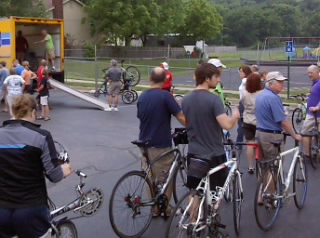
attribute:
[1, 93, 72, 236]
woman — standing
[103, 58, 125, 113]
man — standing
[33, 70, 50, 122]
girl — standing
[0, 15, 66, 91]
truck — for loading bikes on, yellow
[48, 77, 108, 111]
truck ramp — aluminum, for loading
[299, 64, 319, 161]
man — standing, balding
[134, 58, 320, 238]
people — standing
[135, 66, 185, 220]
man — balding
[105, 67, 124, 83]
shirt — gray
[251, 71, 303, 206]
man — older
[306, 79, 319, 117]
shirt — purple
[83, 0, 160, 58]
tree — leafy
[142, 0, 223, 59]
tree — leafy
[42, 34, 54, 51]
shirt — lime green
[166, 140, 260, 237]
bicycle — white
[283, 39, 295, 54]
sign — blue, white